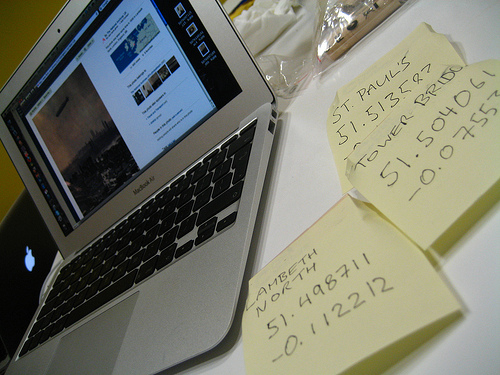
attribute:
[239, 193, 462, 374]
post it note — yellow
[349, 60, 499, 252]
post it note — yellow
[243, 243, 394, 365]
writing — black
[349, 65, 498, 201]
writing — black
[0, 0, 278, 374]
laptop — grey, black, silver, turned on, gray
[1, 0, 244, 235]
screen — lit, turned on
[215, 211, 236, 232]
key — black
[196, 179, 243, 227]
key — black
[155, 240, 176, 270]
key — black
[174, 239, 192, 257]
key — black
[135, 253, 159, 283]
key — black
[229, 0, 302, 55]
napkin — white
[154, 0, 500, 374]
table — white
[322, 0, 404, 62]
object — brown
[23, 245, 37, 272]
mac logo — white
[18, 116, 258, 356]
keyboard — black